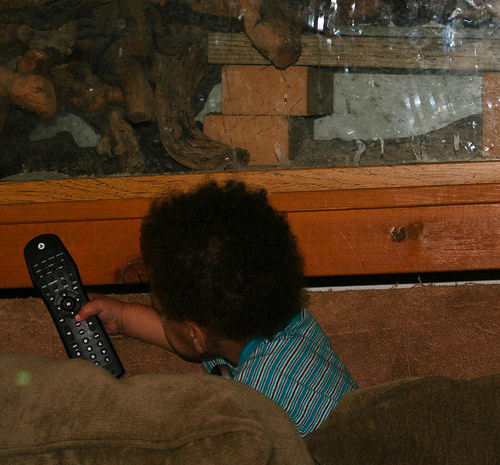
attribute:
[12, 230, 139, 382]
remote — black, long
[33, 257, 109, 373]
buttons — white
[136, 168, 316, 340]
hair — black, curly, dark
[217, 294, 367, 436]
shirt — striped, blue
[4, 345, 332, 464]
cushions — brown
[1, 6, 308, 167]
logs — wood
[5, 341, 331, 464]
cushion — brown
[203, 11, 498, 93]
wood — straight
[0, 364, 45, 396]
spot — green